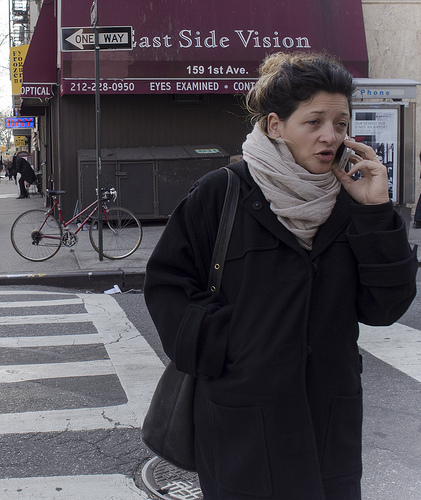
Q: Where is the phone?
A: On her ear.